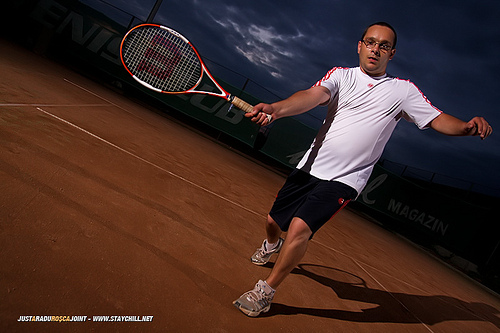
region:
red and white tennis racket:
[111, 18, 276, 127]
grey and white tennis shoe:
[227, 275, 279, 321]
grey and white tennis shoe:
[246, 232, 288, 269]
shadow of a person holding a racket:
[235, 243, 498, 330]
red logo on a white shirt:
[363, 79, 376, 91]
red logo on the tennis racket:
[130, 29, 185, 84]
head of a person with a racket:
[350, 19, 406, 74]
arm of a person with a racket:
[242, 65, 349, 135]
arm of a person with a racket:
[403, 77, 495, 161]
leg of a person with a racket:
[227, 175, 367, 320]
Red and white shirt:
[292, 65, 442, 201]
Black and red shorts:
[266, 165, 356, 240]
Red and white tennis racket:
[116, 20, 271, 122]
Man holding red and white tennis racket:
[115, 20, 490, 317]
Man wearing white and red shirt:
[230, 20, 491, 318]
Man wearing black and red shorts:
[231, 19, 493, 317]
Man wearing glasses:
[231, 20, 492, 318]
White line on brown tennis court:
[34, 104, 351, 311]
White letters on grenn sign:
[40, 0, 250, 125]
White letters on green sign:
[386, 196, 449, 236]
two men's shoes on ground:
[233, 223, 295, 323]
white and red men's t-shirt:
[302, 54, 447, 216]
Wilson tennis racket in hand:
[95, 23, 280, 133]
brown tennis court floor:
[8, 69, 121, 203]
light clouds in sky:
[223, 7, 299, 74]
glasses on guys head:
[352, 32, 399, 55]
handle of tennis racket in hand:
[233, 92, 282, 132]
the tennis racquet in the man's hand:
[121, 21, 273, 126]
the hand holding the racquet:
[245, 102, 274, 127]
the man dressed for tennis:
[120, 20, 491, 316]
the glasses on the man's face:
[360, 37, 394, 52]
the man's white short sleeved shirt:
[293, 65, 442, 200]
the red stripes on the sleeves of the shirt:
[311, 64, 441, 130]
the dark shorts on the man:
[270, 163, 357, 238]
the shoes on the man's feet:
[233, 235, 277, 315]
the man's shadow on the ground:
[256, 258, 498, 331]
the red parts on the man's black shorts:
[267, 167, 352, 240]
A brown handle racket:
[118, 41, 266, 160]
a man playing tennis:
[265, 11, 499, 313]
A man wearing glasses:
[345, 29, 420, 163]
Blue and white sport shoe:
[215, 264, 290, 326]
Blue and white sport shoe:
[243, 234, 282, 257]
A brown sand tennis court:
[56, 223, 218, 330]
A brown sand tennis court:
[307, 276, 399, 331]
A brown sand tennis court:
[51, 116, 211, 185]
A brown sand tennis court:
[162, 134, 234, 261]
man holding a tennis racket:
[110, 12, 491, 325]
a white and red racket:
[109, 26, 265, 127]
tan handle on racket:
[229, 91, 268, 122]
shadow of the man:
[285, 240, 484, 330]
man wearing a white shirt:
[272, 65, 445, 187]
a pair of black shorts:
[237, 158, 365, 249]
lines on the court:
[14, 82, 229, 236]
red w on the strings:
[136, 32, 181, 89]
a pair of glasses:
[354, 33, 394, 62]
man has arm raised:
[392, 74, 497, 159]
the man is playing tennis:
[119, 8, 494, 315]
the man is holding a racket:
[117, 15, 276, 142]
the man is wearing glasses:
[361, 32, 393, 55]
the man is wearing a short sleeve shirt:
[303, 63, 438, 199]